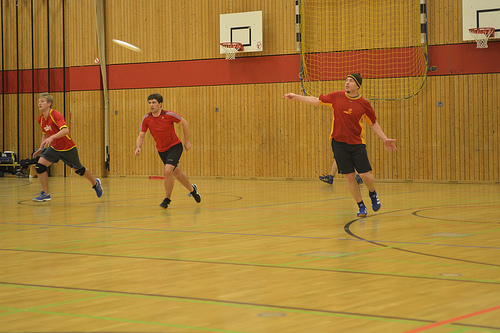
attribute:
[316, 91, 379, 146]
shirt — man's,  red and yellow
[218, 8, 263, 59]
backboard —  white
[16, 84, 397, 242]
men —  Young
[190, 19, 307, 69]
hoop —  for basketball,  one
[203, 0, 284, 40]
backboard —  white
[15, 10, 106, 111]
beams —  wooden, Brown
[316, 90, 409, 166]
shirt —   red and yellow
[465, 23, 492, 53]
hoop —  on  right, for basketball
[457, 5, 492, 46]
backboard —  on  right, for basketball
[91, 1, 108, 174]
curtain — a divider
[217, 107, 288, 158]
wall —  paneled,  wood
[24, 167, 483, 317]
court — Basketball's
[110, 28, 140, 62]
frisbee —  in midair,  one,  white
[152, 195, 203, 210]
shoes —  Black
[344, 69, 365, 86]
knit hat —  knit 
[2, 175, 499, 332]
court — for basketball, hardwood,  surface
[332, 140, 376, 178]
shorts —  black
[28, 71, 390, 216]
players —   for sports,  Three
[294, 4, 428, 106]
net —  large 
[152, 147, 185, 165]
shorts —  Black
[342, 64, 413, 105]
cap —  black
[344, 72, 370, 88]
hat —  knit ,   black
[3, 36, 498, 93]
line —  thick ,  red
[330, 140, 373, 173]
shorts —  dark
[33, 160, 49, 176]
guards —  black,  for knee